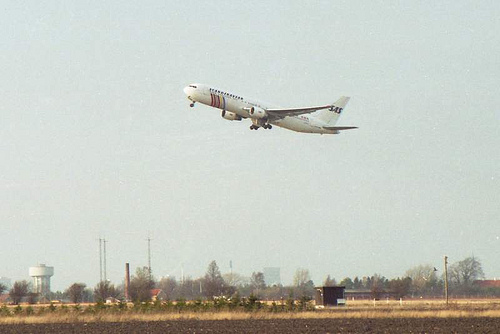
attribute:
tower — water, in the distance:
[29, 265, 61, 301]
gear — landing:
[189, 97, 200, 108]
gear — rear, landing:
[244, 121, 274, 134]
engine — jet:
[243, 104, 267, 124]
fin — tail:
[318, 95, 358, 125]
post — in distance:
[102, 235, 111, 301]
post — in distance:
[94, 236, 105, 302]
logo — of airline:
[326, 103, 346, 120]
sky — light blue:
[7, 8, 493, 265]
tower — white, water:
[27, 260, 58, 302]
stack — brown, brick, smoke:
[119, 262, 137, 310]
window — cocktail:
[205, 84, 245, 108]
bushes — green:
[4, 303, 316, 315]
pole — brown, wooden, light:
[442, 250, 453, 302]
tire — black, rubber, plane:
[249, 122, 258, 132]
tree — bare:
[444, 255, 487, 297]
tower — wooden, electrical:
[101, 238, 113, 302]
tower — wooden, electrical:
[96, 232, 106, 299]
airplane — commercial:
[177, 75, 360, 147]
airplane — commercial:
[177, 77, 365, 140]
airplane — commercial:
[175, 69, 358, 144]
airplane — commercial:
[179, 76, 365, 152]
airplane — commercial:
[189, 82, 346, 141]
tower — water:
[24, 251, 75, 301]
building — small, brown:
[311, 279, 373, 320]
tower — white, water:
[15, 261, 68, 302]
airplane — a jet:
[154, 57, 388, 191]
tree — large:
[416, 245, 479, 315]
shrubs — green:
[99, 286, 351, 326]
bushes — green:
[98, 278, 293, 328]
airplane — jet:
[189, 69, 362, 163]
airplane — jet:
[157, 66, 355, 161]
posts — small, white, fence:
[357, 278, 399, 314]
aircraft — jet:
[253, 88, 326, 124]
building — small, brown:
[313, 278, 351, 312]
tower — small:
[17, 259, 74, 318]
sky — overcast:
[66, 109, 116, 185]